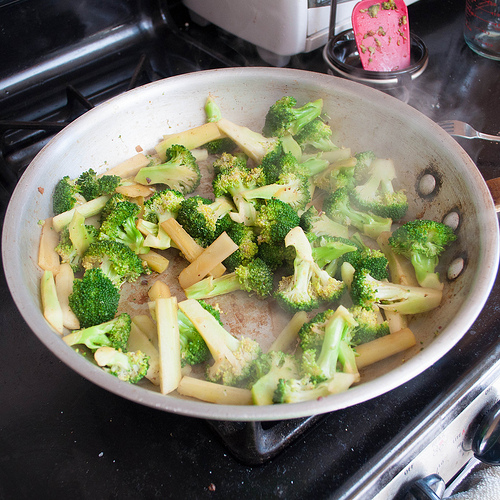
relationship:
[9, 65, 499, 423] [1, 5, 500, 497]
pan on stove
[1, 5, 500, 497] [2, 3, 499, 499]
stove in kitchen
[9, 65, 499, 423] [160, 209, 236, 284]
pan has potatoes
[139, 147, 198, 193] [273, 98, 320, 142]
broccoli in pieces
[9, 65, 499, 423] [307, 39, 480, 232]
pan has steam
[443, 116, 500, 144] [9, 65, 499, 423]
fork next to pan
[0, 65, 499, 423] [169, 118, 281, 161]
pan has noodles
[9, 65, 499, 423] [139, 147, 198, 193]
pan has broccoli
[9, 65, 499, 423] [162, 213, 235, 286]
pan has bamboo shoots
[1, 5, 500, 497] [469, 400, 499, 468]
stove has controls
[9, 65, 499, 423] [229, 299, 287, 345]
pan has brown stuff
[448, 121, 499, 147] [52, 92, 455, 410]
utensil for stir fry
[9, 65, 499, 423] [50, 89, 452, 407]
pan has vegetables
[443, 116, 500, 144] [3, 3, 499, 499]
fork on counter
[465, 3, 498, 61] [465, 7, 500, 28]
cup for measuring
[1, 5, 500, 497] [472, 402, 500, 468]
stove has knobs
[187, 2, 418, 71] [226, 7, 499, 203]
appliance on counter